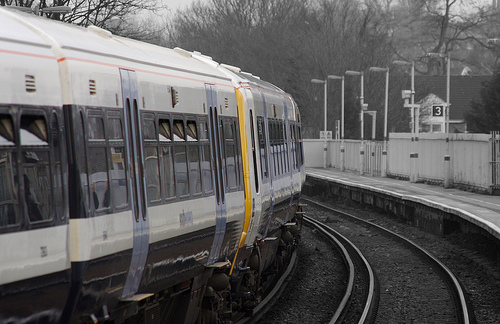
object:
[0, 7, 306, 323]
train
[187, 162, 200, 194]
passengers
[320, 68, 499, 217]
train stop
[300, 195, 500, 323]
railway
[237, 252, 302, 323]
curve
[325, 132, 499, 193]
fence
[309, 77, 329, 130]
lamps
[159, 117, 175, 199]
window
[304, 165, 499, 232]
ground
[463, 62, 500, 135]
trees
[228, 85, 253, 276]
stripe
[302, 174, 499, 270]
ledge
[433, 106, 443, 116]
number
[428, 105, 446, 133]
sign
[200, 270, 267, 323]
wheels